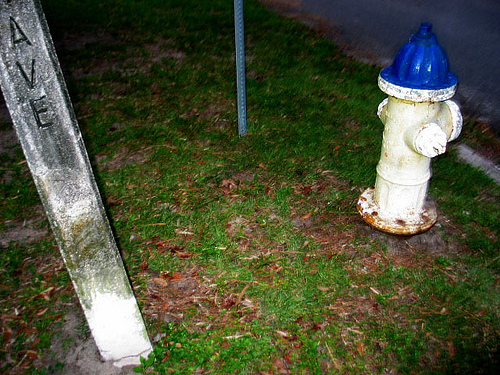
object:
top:
[377, 22, 460, 92]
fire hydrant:
[357, 21, 465, 236]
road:
[296, 0, 500, 185]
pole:
[232, 0, 246, 134]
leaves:
[152, 267, 250, 324]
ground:
[0, 0, 500, 375]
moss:
[50, 207, 139, 310]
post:
[1, 0, 151, 362]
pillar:
[0, 0, 158, 366]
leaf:
[170, 247, 199, 260]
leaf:
[239, 291, 257, 312]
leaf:
[339, 302, 355, 318]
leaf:
[348, 336, 369, 356]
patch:
[48, 309, 84, 361]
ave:
[1, 11, 59, 131]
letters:
[7, 15, 55, 131]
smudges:
[75, 273, 154, 365]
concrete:
[344, 11, 485, 49]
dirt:
[64, 338, 114, 372]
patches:
[155, 271, 260, 325]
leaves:
[170, 284, 237, 327]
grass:
[2, 2, 500, 375]